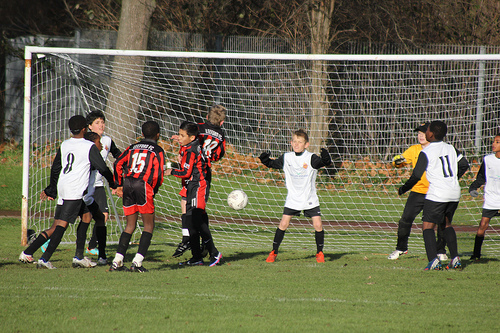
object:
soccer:
[225, 189, 249, 212]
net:
[21, 54, 500, 255]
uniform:
[112, 140, 166, 258]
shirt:
[390, 144, 436, 194]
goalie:
[389, 117, 458, 264]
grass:
[0, 158, 499, 332]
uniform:
[49, 136, 116, 263]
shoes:
[265, 249, 279, 263]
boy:
[258, 128, 332, 263]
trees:
[59, 0, 188, 154]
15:
[129, 152, 148, 173]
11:
[439, 154, 454, 178]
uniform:
[399, 141, 469, 261]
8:
[62, 152, 76, 175]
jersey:
[54, 137, 99, 206]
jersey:
[110, 138, 162, 192]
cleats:
[74, 221, 89, 260]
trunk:
[97, 0, 161, 153]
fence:
[0, 29, 500, 163]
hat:
[413, 122, 431, 133]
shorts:
[281, 206, 321, 219]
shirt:
[282, 151, 320, 212]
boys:
[107, 121, 167, 274]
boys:
[33, 114, 122, 269]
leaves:
[215, 154, 248, 172]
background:
[3, 0, 500, 156]